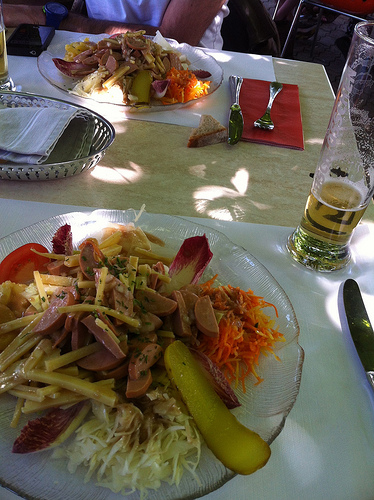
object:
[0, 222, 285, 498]
antipasto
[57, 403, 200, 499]
cheese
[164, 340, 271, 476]
pickle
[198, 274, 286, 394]
carrots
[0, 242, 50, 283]
tomato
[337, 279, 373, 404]
knife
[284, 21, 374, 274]
glass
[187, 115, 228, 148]
bread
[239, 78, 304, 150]
napkin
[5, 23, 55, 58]
cell phone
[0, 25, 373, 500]
table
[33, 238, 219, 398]
hot dog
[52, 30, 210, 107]
plate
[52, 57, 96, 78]
tomato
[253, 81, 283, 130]
fork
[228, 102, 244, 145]
butter knife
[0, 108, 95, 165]
napkin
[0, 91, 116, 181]
basket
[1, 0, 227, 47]
person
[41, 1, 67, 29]
black watch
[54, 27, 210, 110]
meat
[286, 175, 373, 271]
beer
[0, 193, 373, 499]
placemat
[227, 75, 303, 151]
utensils